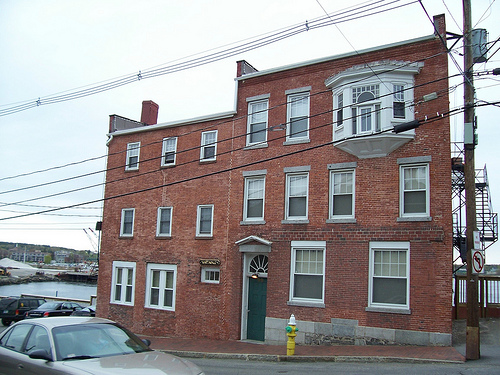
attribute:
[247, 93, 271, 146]
window — glass, white, large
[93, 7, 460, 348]
building — brick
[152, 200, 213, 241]
windows — painted, white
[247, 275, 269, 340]
door — green, dark green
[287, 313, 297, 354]
fire hydrant — yellow, green, white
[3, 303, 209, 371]
car — cream, grey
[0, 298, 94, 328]
row — cars, brown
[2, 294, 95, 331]
cars — parked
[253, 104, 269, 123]
lines — white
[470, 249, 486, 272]
sign — red, white, black, "no left turn"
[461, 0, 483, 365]
post — electrical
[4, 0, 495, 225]
wires — hanging, electrical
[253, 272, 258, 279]
light bulb — oln, on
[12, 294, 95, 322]
wall — brick, brown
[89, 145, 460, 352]
house — red, brick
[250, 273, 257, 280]
light — small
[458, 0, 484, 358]
telephone pole — brown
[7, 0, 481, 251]
sky — blue, grey